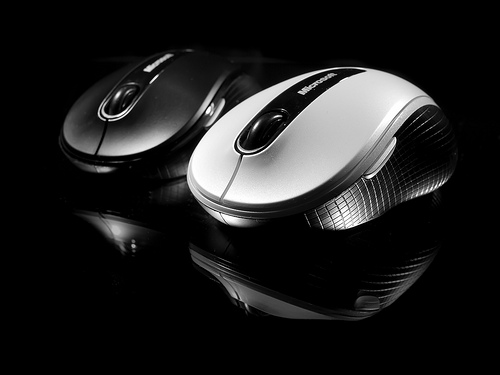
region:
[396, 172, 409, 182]
part of a mouse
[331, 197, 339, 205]
edge of a mouse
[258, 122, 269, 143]
part of a rolling ball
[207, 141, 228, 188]
part of a mouse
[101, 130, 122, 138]
edge of a mouse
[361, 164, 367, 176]
black part on a mouse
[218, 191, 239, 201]
part of a mouse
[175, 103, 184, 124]
edge of a mouse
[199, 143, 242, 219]
part of a mouse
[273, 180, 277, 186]
bottom of a mouse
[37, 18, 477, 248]
a set of two Microsoft computer mouses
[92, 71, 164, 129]
a black mouse roller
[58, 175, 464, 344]
the reflection of two computer mouses on sleek surface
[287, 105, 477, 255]
the textured side of a computer mouse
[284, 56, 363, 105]
the Microsoft logo on a computer mouse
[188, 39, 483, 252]
a white and black computer mouse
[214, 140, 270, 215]
the break between left and right click buttons on computer mouse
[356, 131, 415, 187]
the white side button on a computer mouse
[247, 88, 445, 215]
the side curve of a computer mouse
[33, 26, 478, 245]
display of two computer mouse color options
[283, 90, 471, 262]
Black crisscross pattern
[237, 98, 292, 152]
Black rolling mouse wheel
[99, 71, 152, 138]
Black scrolling mouse wheel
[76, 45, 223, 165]
Mouse is black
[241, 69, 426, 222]
Mouse is silver and black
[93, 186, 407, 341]
Reflection of mouse on table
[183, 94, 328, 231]
Mouse has two buttons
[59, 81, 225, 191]
Mouse has two buttons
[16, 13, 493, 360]
Mouse on black background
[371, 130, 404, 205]
Mouse has small tab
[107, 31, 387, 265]
an optical mouse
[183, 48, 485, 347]
an optical mouse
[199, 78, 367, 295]
an optical mouse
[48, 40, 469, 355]
black and white objects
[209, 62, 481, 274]
white microsoft mouse with black button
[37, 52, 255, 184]
black microsoft mouse with black button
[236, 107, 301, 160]
black roller button on mouse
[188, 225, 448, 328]
reflection of mouse on desk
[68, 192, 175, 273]
reflection of mouse on table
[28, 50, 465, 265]
two computer mouses on desk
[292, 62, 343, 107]
MIcrosoft logo on a mouse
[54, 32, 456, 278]
mouse on display for sale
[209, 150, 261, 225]
line in the mouse